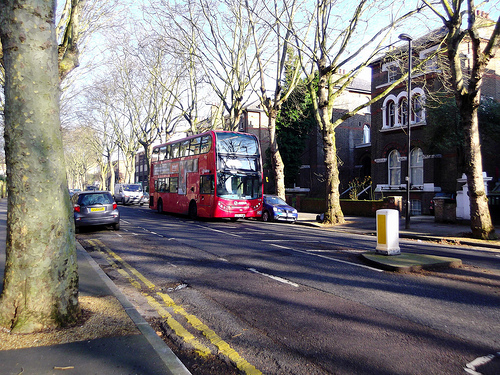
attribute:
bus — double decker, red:
[150, 132, 267, 220]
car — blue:
[76, 189, 123, 233]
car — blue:
[264, 195, 298, 222]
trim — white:
[382, 88, 427, 132]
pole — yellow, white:
[377, 208, 400, 257]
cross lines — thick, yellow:
[82, 234, 262, 374]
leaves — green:
[287, 60, 313, 183]